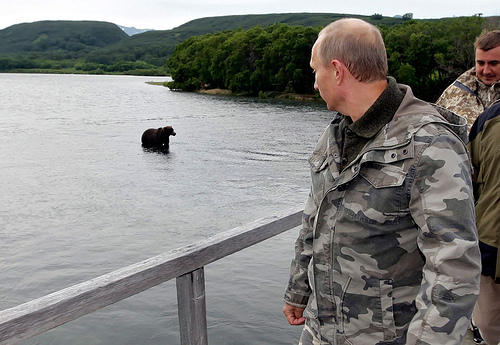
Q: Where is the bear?
A: In water.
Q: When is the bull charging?
A: No bull.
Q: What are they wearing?
A: Camouflage.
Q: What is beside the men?
A: Rail.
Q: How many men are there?
A: Two.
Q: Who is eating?
A: No one.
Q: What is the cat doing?
A: No cat.